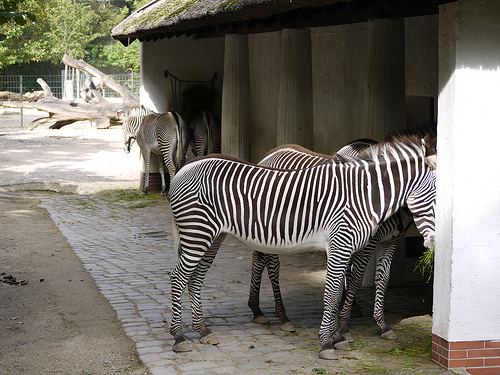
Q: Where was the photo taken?
A: A zoo.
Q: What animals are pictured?
A: Zebras.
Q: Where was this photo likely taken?
A: Zoo.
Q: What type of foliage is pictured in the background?
A: Trees.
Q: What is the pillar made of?
A: Cement.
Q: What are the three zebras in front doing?
A: Eating.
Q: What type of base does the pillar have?
A: Brick.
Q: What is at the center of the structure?
A: 3 pillars.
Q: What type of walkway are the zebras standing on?
A: Cobblestone.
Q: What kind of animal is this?
A: Zebra.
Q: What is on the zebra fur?
A: Striped pattern.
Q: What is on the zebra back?
A: Black and white mane.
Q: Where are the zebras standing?
A: Sidewalk.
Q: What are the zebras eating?
A: Grass.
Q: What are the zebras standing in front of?
A: Stone building.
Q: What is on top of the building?
A: Thatched roof.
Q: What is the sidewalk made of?
A: Cobblestones.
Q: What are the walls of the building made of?
A: Stone.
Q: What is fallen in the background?
A: Tree log.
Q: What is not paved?
A: The ground.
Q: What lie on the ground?
A: Tree trunks.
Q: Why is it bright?
A: The sun is shining.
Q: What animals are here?
A: Zebras.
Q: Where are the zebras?
A: In the pen.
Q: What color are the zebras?
A: Black and white.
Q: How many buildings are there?
A: One.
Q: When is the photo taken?
A: Daytime.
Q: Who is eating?
A: A zebra.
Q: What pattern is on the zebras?
A: Stripes.